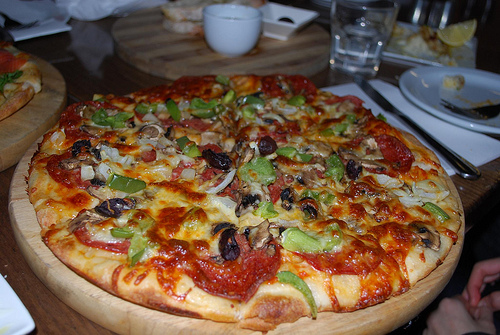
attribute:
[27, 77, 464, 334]
pizza — delicious looking, round, whole pizza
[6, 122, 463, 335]
platform — wooden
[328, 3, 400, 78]
glass — clear, empty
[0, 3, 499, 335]
table — brown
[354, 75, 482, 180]
knife — here, butter knife, metal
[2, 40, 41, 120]
pizza — another, in the corner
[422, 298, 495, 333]
hand — below, here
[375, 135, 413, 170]
topping — red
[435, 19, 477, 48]
wedge — lemon, yellow, a slice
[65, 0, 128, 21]
cup — white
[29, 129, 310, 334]
crust — brown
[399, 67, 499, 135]
plate — white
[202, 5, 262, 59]
bowl — white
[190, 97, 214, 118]
pepper — green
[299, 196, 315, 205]
olive — black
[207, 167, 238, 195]
onion — white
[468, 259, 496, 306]
finger — here